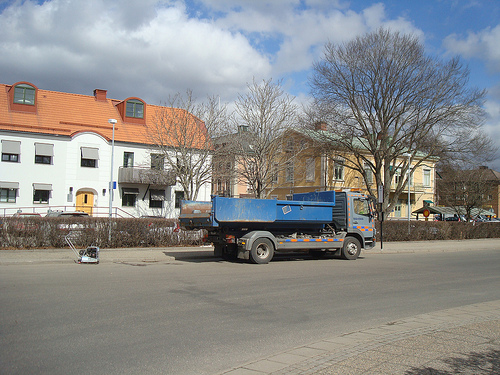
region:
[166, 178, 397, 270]
truck on the road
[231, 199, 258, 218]
blue paint is fading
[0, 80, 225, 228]
white building with an orange roof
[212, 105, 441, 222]
yellow building with a green roof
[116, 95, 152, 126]
window on the roof of the building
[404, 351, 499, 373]
shadow on the road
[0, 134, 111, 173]
three windows on the side of the building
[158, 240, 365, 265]
shadow from the truck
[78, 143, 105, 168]
gray awning on the window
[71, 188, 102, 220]
yellow door on the building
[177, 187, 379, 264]
A blue transit truck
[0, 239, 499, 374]
A large tarmacked road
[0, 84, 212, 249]
The white painted building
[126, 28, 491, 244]
The leafless trees behind the fence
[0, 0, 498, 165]
A blue clouded sky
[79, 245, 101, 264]
An object on the side walk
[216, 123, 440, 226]
The brown painted buildings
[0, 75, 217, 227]
The red tiled building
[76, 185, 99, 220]
A brown front door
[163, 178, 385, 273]
truck on the road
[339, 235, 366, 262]
wheel on the front of the truck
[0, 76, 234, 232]
white building with an orange roof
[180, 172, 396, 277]
blue and red truck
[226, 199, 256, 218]
blue paint is fading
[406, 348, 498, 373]
shadows on the ground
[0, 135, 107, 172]
row of three windows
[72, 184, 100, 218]
yellow door on the front of the building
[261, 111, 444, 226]
yellow building with a green roof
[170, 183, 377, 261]
dump truck with a blue bed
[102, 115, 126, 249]
tall lantern on sidewalk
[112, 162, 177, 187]
balcony of an apartment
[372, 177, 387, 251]
small sign on side of road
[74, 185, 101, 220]
yellow door of a white building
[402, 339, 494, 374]
shadow on sidewalk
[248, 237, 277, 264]
tire of a dumptruck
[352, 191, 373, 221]
front window of cab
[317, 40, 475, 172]
part of a tree with no leaves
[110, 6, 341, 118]
fluffy white clouds in the sky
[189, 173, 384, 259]
vehicle on the road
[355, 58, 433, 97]
branches on the tree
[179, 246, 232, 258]
shadow of the vehicle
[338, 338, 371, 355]
the sidewalk is concrete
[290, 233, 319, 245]
stripes on the truck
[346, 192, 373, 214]
window of the truck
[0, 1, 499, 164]
A blue sky full of grey clouds.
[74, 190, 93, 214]
A yellow door on a large white building.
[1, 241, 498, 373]
A grey paved road.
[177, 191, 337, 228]
A blue metal truck bed.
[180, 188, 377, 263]
A large blue and grey truck.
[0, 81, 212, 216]
A white building with red roof.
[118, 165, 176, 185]
Grey balcony on a white building.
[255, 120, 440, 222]
Yellow building with green roof and red chimney.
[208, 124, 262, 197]
Peach colored house with grey roof.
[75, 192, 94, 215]
A big orange door with black window.